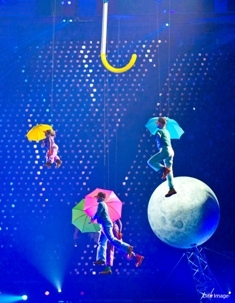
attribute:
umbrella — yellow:
[24, 124, 51, 140]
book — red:
[48, 149, 52, 154]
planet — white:
[147, 175, 220, 247]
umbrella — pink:
[81, 184, 124, 226]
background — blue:
[14, 15, 233, 125]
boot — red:
[128, 245, 149, 271]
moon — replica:
[146, 175, 221, 249]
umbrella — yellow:
[23, 123, 56, 142]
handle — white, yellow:
[85, 34, 154, 96]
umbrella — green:
[71, 198, 99, 234]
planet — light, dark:
[128, 173, 230, 257]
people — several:
[147, 112, 181, 196]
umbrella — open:
[143, 115, 184, 141]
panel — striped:
[55, 69, 129, 154]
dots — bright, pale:
[80, 45, 86, 49]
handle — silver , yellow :
[100, 0, 136, 72]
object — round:
[90, 30, 150, 81]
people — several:
[8, 114, 178, 268]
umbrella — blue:
[148, 113, 180, 137]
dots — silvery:
[10, 38, 211, 278]